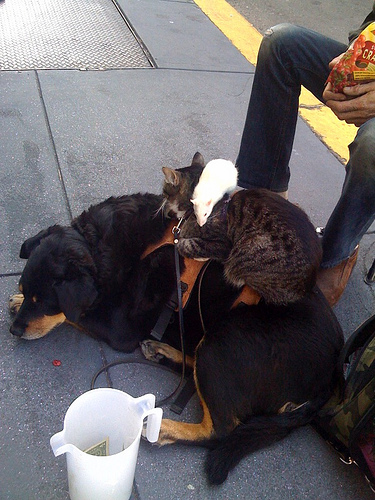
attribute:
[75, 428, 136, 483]
dollar bill — green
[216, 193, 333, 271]
dog — dark coat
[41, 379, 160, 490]
pitcher — white